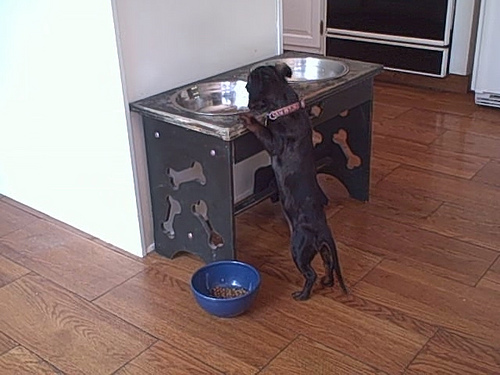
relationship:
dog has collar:
[243, 51, 347, 302] [263, 77, 333, 131]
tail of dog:
[321, 240, 358, 300] [243, 51, 347, 302]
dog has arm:
[243, 51, 347, 302] [242, 106, 268, 157]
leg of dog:
[295, 223, 327, 321] [243, 51, 347, 302]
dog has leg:
[243, 51, 347, 302] [295, 223, 327, 321]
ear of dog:
[278, 62, 296, 82] [243, 51, 347, 302]